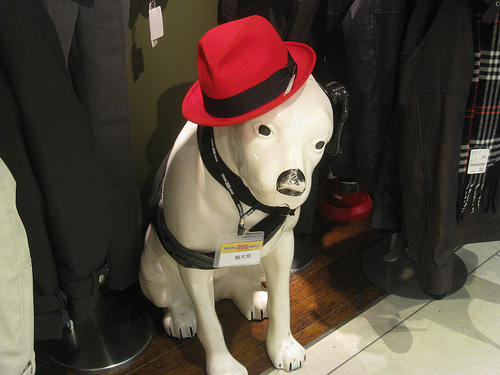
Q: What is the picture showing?
A: It is showing a store.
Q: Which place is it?
A: It is a store.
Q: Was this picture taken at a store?
A: Yes, it was taken in a store.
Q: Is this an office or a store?
A: It is a store.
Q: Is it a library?
A: No, it is a store.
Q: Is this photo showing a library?
A: No, the picture is showing a store.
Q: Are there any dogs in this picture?
A: Yes, there is a dog.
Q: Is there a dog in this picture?
A: Yes, there is a dog.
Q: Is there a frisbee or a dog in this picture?
A: Yes, there is a dog.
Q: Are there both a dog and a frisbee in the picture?
A: No, there is a dog but no frisbees.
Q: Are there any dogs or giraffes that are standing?
A: Yes, the dog is standing.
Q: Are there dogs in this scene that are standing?
A: Yes, there is a dog that is standing.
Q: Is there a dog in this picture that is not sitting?
A: Yes, there is a dog that is standing.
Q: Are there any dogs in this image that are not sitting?
A: Yes, there is a dog that is standing.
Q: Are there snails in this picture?
A: No, there are no snails.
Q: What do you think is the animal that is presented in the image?
A: The animal is a dog.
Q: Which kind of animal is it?
A: The animal is a dog.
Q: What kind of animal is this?
A: That is a dog.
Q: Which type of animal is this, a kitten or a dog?
A: That is a dog.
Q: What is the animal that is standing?
A: The animal is a dog.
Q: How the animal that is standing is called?
A: The animal is a dog.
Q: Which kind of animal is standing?
A: The animal is a dog.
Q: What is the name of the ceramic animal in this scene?
A: The animal is a dog.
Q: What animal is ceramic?
A: The animal is a dog.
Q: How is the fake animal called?
A: The animal is a dog.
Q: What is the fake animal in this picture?
A: The animal is a dog.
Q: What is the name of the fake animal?
A: The animal is a dog.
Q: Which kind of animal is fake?
A: The animal is a dog.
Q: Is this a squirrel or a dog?
A: This is a dog.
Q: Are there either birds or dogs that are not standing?
A: No, there is a dog but it is standing.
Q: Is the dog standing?
A: Yes, the dog is standing.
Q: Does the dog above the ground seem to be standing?
A: Yes, the dog is standing.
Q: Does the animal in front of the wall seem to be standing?
A: Yes, the dog is standing.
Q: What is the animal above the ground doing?
A: The dog is standing.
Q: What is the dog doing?
A: The dog is standing.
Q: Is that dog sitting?
A: No, the dog is standing.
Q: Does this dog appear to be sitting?
A: No, the dog is standing.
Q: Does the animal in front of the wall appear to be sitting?
A: No, the dog is standing.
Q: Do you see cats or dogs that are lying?
A: No, there is a dog but it is standing.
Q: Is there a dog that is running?
A: No, there is a dog but it is standing.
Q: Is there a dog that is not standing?
A: No, there is a dog but it is standing.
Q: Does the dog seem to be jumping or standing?
A: The dog is standing.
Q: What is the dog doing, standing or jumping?
A: The dog is standing.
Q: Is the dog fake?
A: Yes, the dog is fake.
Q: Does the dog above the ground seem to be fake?
A: Yes, the dog is fake.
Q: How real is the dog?
A: The dog is fake.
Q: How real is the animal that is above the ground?
A: The dog is fake.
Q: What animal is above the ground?
A: The animal is a dog.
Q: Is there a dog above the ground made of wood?
A: Yes, there is a dog above the ground.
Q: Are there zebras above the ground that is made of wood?
A: No, there is a dog above the ground.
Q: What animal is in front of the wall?
A: The dog is in front of the wall.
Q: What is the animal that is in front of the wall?
A: The animal is a dog.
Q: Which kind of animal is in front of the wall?
A: The animal is a dog.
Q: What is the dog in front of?
A: The dog is in front of the wall.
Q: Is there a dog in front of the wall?
A: Yes, there is a dog in front of the wall.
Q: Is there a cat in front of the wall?
A: No, there is a dog in front of the wall.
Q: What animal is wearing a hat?
A: The dog is wearing a hat.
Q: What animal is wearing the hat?
A: The dog is wearing a hat.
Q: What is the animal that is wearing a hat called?
A: The animal is a dog.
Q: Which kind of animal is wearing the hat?
A: The animal is a dog.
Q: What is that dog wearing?
A: The dog is wearing a hat.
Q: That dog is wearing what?
A: The dog is wearing a hat.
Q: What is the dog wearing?
A: The dog is wearing a hat.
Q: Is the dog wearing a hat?
A: Yes, the dog is wearing a hat.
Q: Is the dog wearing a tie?
A: No, the dog is wearing a hat.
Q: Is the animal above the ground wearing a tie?
A: No, the dog is wearing a hat.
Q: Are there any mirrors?
A: No, there are no mirrors.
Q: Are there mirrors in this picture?
A: No, there are no mirrors.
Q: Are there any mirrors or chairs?
A: No, there are no mirrors or chairs.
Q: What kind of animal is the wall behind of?
A: The wall is behind the dog.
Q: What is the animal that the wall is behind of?
A: The animal is a dog.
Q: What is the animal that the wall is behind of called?
A: The animal is a dog.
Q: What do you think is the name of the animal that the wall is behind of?
A: The animal is a dog.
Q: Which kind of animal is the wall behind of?
A: The wall is behind the dog.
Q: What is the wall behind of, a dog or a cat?
A: The wall is behind a dog.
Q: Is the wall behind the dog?
A: Yes, the wall is behind the dog.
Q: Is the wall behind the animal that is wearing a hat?
A: Yes, the wall is behind the dog.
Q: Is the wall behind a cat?
A: No, the wall is behind the dog.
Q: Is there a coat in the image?
A: Yes, there is a coat.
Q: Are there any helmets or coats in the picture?
A: Yes, there is a coat.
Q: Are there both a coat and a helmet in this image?
A: No, there is a coat but no helmets.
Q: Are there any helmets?
A: No, there are no helmets.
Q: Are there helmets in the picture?
A: No, there are no helmets.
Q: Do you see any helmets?
A: No, there are no helmets.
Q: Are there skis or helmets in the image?
A: No, there are no helmets or skis.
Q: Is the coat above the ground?
A: Yes, the coat is above the ground.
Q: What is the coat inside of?
A: The coat is inside the store.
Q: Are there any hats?
A: Yes, there is a hat.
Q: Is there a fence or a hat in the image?
A: Yes, there is a hat.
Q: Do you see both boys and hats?
A: No, there is a hat but no boys.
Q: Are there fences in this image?
A: No, there are no fences.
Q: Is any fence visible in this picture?
A: No, there are no fences.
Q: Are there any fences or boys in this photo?
A: No, there are no fences or boys.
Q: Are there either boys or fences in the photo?
A: No, there are no fences or boys.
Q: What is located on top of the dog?
A: The hat is on top of the dog.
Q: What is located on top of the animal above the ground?
A: The hat is on top of the dog.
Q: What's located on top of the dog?
A: The hat is on top of the dog.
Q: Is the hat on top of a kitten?
A: No, the hat is on top of the dog.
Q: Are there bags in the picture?
A: No, there are no bags.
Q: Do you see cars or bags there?
A: No, there are no bags or cars.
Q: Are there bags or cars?
A: No, there are no bags or cars.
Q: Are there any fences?
A: No, there are no fences.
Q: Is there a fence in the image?
A: No, there are no fences.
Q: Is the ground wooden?
A: Yes, the ground is wooden.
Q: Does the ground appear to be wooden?
A: Yes, the ground is wooden.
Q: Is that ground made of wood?
A: Yes, the ground is made of wood.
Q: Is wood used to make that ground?
A: Yes, the ground is made of wood.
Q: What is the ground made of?
A: The ground is made of wood.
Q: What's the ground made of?
A: The ground is made of wood.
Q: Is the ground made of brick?
A: No, the ground is made of wood.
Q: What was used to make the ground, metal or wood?
A: The ground is made of wood.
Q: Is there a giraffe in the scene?
A: No, there are no giraffes.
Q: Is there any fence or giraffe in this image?
A: No, there are no giraffes or fences.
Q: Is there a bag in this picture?
A: No, there are no bags.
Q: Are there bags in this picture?
A: No, there are no bags.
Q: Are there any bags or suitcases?
A: No, there are no bags or suitcases.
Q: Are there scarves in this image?
A: Yes, there is a scarf.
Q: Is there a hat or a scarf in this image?
A: Yes, there is a scarf.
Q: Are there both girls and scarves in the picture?
A: No, there is a scarf but no girls.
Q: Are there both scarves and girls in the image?
A: No, there is a scarf but no girls.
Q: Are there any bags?
A: No, there are no bags.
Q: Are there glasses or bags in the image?
A: No, there are no bags or glasses.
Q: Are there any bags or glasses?
A: No, there are no bags or glasses.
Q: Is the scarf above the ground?
A: Yes, the scarf is above the ground.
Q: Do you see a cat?
A: No, there are no cats.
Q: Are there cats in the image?
A: No, there are no cats.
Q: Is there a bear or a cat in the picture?
A: No, there are no cats or bears.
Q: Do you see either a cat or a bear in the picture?
A: No, there are no cats or bears.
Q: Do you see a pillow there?
A: No, there are no pillows.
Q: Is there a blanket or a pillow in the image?
A: No, there are no pillows or blankets.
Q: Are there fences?
A: No, there are no fences.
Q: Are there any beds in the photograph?
A: No, there are no beds.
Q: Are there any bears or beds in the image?
A: No, there are no beds or bears.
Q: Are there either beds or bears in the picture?
A: No, there are no beds or bears.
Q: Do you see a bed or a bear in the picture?
A: No, there are no beds or bears.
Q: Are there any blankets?
A: No, there are no blankets.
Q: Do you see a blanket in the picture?
A: No, there are no blankets.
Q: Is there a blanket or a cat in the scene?
A: No, there are no blankets or cats.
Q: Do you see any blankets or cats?
A: No, there are no blankets or cats.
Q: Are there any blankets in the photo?
A: No, there are no blankets.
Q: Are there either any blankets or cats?
A: No, there are no blankets or cats.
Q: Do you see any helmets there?
A: No, there are no helmets.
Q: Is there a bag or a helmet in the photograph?
A: No, there are no helmets or bags.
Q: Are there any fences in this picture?
A: No, there are no fences.